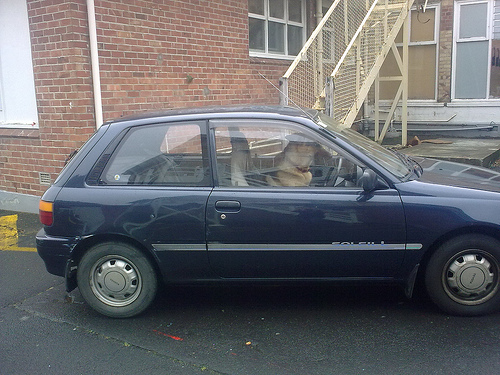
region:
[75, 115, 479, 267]
The car is blue.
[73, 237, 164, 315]
The tire is black.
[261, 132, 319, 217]
The dog is in the car.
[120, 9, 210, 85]
The buiding is brick.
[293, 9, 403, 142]
The stairway is metal.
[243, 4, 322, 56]
The window is white.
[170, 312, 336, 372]
The ground is black.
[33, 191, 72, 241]
The light is red.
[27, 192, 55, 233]
The light is orange.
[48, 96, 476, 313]
The car is parked.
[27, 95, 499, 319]
an older parked blue vehicle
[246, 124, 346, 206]
a German shepard alone inside a car with the windows rolled up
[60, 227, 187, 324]
a well worn car tire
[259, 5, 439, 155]
an outdoor metal staircase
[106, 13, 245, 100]
the red brick exterior of a building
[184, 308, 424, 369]
the black asphalt of a parking lot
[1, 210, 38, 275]
a yellow stripe in a parking lot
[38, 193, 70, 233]
the red and yellow tail light of a car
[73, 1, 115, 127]
a pipe on the exterior of a building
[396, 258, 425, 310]
a mudflap behind the front tire of a vehicle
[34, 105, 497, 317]
a small blue car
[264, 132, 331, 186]
A german shepherd dog in a car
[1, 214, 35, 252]
Yellow paint on the pavement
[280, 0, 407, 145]
A white metal staircase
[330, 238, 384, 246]
Car name on the side of the car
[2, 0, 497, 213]
A red brick building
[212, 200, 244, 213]
A handle on a car door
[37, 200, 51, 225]
A yellow and red tail light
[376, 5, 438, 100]
A window covered by a brown shade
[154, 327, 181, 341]
A red streak on the pavement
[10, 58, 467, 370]
car on a street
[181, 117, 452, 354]
car on a street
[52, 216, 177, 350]
the back car tire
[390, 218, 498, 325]
the front car tire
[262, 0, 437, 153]
a section of stairs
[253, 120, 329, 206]
a big brown dog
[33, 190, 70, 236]
the orange tail light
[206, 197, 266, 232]
the blue door handle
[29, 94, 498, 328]
this is a blue car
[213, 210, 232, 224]
this is a key hole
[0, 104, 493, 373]
this is the concrete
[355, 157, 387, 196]
this is a mirror